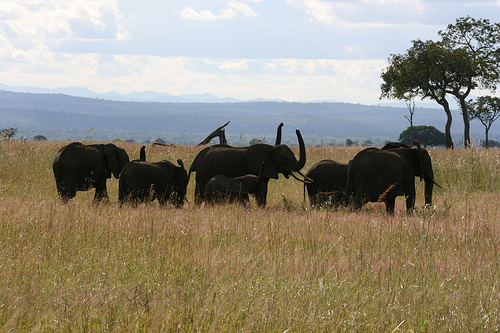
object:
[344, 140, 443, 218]
elephant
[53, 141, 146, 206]
elephant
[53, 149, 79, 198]
elephant's rear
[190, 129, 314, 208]
elephant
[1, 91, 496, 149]
land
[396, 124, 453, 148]
trees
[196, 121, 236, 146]
tree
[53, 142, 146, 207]
animals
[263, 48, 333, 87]
blue sky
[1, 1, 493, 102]
clouds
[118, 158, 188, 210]
elephant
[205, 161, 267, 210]
elephant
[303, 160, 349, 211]
elephant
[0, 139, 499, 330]
brown grass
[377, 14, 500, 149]
tree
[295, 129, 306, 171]
trunk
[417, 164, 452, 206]
hanging trunk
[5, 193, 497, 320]
ground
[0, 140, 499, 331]
plain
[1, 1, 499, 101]
sky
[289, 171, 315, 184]
tusks